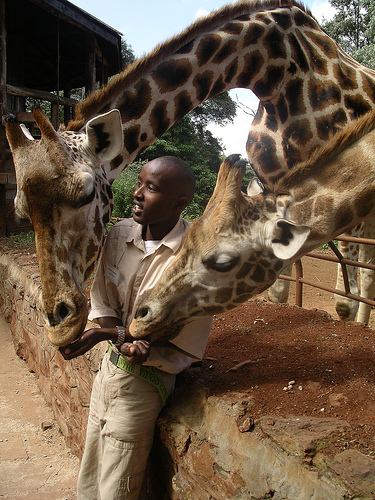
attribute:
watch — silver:
[113, 326, 125, 342]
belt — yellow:
[92, 346, 171, 399]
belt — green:
[100, 337, 173, 402]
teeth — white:
[132, 204, 145, 216]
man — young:
[56, 152, 215, 499]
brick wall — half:
[0, 244, 362, 497]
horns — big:
[205, 153, 248, 231]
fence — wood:
[270, 246, 355, 308]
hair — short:
[149, 154, 194, 178]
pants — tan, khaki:
[76, 343, 176, 497]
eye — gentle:
[212, 242, 254, 282]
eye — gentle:
[66, 166, 108, 211]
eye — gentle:
[11, 191, 36, 238]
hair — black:
[156, 145, 207, 186]